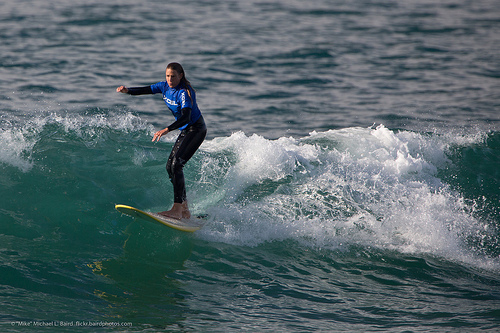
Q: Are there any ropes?
A: No, there are no ropes.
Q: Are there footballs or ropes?
A: No, there are no ropes or footballs.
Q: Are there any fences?
A: No, there are no fences.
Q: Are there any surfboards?
A: Yes, there is a surfboard.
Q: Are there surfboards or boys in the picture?
A: Yes, there is a surfboard.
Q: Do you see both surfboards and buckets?
A: No, there is a surfboard but no buckets.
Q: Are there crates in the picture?
A: No, there are no crates.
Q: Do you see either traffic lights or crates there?
A: No, there are no crates or traffic lights.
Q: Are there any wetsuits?
A: Yes, there is a wetsuit.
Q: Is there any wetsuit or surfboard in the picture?
A: Yes, there is a wetsuit.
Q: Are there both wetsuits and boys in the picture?
A: No, there is a wetsuit but no boys.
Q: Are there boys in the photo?
A: No, there are no boys.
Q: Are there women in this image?
A: Yes, there is a woman.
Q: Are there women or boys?
A: Yes, there is a woman.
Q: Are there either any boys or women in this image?
A: Yes, there is a woman.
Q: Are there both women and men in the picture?
A: No, there is a woman but no men.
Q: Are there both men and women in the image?
A: No, there is a woman but no men.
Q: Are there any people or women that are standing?
A: Yes, the woman is standing.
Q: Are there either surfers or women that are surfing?
A: Yes, the woman is surfing.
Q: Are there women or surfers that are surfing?
A: Yes, the woman is surfing.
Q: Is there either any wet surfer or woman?
A: Yes, there is a wet woman.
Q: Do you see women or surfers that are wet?
A: Yes, the woman is wet.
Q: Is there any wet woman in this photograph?
A: Yes, there is a wet woman.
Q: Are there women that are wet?
A: Yes, there is a woman that is wet.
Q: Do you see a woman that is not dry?
A: Yes, there is a wet woman.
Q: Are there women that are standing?
A: Yes, there is a woman that is standing.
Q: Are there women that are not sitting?
A: Yes, there is a woman that is standing.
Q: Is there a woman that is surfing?
A: Yes, there is a woman that is surfing.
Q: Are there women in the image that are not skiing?
A: Yes, there is a woman that is surfing.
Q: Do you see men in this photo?
A: No, there are no men.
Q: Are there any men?
A: No, there are no men.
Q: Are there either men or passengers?
A: No, there are no men or passengers.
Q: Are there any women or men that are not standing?
A: No, there is a woman but she is standing.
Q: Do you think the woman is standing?
A: Yes, the woman is standing.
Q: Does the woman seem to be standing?
A: Yes, the woman is standing.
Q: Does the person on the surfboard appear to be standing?
A: Yes, the woman is standing.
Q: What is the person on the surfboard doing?
A: The woman is standing.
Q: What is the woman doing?
A: The woman is standing.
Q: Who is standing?
A: The woman is standing.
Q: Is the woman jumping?
A: No, the woman is standing.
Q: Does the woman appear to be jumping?
A: No, the woman is standing.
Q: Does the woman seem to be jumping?
A: No, the woman is standing.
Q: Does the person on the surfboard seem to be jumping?
A: No, the woman is standing.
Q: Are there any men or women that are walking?
A: No, there is a woman but she is standing.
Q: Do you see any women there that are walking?
A: No, there is a woman but she is standing.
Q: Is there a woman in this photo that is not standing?
A: No, there is a woman but she is standing.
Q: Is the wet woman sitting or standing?
A: The woman is standing.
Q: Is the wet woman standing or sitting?
A: The woman is standing.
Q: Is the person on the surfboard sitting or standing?
A: The woman is standing.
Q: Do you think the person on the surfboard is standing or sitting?
A: The woman is standing.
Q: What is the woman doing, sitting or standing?
A: The woman is standing.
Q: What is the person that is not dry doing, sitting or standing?
A: The woman is standing.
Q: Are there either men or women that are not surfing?
A: No, there is a woman but she is surfing.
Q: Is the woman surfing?
A: Yes, the woman is surfing.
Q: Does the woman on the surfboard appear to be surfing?
A: Yes, the woman is surfing.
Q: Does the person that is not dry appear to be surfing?
A: Yes, the woman is surfing.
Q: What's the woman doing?
A: The woman is surfing.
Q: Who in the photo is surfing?
A: The woman is surfing.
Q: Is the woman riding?
A: No, the woman is surfing.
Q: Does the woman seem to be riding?
A: No, the woman is surfing.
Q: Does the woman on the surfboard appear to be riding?
A: No, the woman is surfing.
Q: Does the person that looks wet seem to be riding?
A: No, the woman is surfing.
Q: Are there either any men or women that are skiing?
A: No, there is a woman but she is surfing.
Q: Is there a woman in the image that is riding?
A: No, there is a woman but she is surfing.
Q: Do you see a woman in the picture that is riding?
A: No, there is a woman but she is surfing.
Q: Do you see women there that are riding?
A: No, there is a woman but she is surfing.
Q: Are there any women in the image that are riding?
A: No, there is a woman but she is surfing.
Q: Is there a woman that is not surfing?
A: No, there is a woman but she is surfing.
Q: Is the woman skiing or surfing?
A: The woman is surfing.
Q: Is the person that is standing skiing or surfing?
A: The woman is surfing.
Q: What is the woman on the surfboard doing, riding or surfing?
A: The woman is surfing.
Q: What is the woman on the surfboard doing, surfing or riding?
A: The woman is surfing.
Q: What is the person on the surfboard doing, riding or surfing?
A: The woman is surfing.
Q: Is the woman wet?
A: Yes, the woman is wet.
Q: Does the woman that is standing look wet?
A: Yes, the woman is wet.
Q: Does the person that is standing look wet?
A: Yes, the woman is wet.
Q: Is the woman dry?
A: No, the woman is wet.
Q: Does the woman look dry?
A: No, the woman is wet.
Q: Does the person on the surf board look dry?
A: No, the woman is wet.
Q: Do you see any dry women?
A: No, there is a woman but she is wet.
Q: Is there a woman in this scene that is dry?
A: No, there is a woman but she is wet.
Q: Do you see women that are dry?
A: No, there is a woman but she is wet.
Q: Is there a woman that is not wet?
A: No, there is a woman but she is wet.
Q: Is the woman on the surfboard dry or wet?
A: The woman is wet.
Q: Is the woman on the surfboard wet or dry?
A: The woman is wet.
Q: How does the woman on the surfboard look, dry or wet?
A: The woman is wet.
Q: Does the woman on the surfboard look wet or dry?
A: The woman is wet.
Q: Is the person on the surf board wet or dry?
A: The woman is wet.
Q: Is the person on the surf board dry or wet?
A: The woman is wet.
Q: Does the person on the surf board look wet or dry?
A: The woman is wet.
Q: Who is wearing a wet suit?
A: The woman is wearing a wet suit.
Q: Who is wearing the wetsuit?
A: The woman is wearing a wet suit.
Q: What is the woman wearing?
A: The woman is wearing a wet suit.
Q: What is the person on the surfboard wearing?
A: The woman is wearing a wet suit.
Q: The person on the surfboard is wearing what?
A: The woman is wearing a wet suit.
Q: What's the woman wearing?
A: The woman is wearing a wet suit.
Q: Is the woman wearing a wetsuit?
A: Yes, the woman is wearing a wetsuit.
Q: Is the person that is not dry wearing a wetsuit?
A: Yes, the woman is wearing a wetsuit.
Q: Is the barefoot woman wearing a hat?
A: No, the woman is wearing a wetsuit.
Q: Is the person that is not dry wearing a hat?
A: No, the woman is wearing a wetsuit.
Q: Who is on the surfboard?
A: The woman is on the surfboard.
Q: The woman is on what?
A: The woman is on the surfboard.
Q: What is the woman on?
A: The woman is on the surfboard.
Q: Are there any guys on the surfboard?
A: No, there is a woman on the surfboard.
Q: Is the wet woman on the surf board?
A: Yes, the woman is on the surf board.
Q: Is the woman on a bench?
A: No, the woman is on the surf board.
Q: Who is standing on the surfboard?
A: The woman is standing on the surfboard.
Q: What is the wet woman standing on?
A: The woman is standing on the surf board.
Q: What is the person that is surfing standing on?
A: The woman is standing on the surf board.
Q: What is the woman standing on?
A: The woman is standing on the surf board.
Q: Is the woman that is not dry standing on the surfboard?
A: Yes, the woman is standing on the surfboard.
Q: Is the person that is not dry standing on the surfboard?
A: Yes, the woman is standing on the surfboard.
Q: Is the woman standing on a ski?
A: No, the woman is standing on the surfboard.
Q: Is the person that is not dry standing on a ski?
A: No, the woman is standing on the surfboard.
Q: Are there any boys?
A: No, there are no boys.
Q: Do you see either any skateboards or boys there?
A: No, there are no boys or skateboards.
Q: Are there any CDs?
A: No, there are no cds.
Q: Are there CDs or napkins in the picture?
A: No, there are no CDs or napkins.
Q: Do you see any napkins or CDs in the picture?
A: No, there are no CDs or napkins.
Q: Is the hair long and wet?
A: Yes, the hair is long and wet.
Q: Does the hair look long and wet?
A: Yes, the hair is long and wet.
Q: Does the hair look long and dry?
A: No, the hair is long but wet.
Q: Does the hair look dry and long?
A: No, the hair is long but wet.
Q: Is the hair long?
A: Yes, the hair is long.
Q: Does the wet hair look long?
A: Yes, the hair is long.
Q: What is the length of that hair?
A: The hair is long.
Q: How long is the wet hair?
A: The hair is long.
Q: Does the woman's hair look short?
A: No, the hair is long.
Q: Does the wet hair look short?
A: No, the hair is long.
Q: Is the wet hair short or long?
A: The hair is long.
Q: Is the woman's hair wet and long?
A: Yes, the hair is wet and long.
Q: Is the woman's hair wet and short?
A: No, the hair is wet but long.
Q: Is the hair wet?
A: Yes, the hair is wet.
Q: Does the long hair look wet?
A: Yes, the hair is wet.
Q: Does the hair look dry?
A: No, the hair is wet.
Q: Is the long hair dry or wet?
A: The hair is wet.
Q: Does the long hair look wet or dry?
A: The hair is wet.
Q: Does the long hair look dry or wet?
A: The hair is wet.